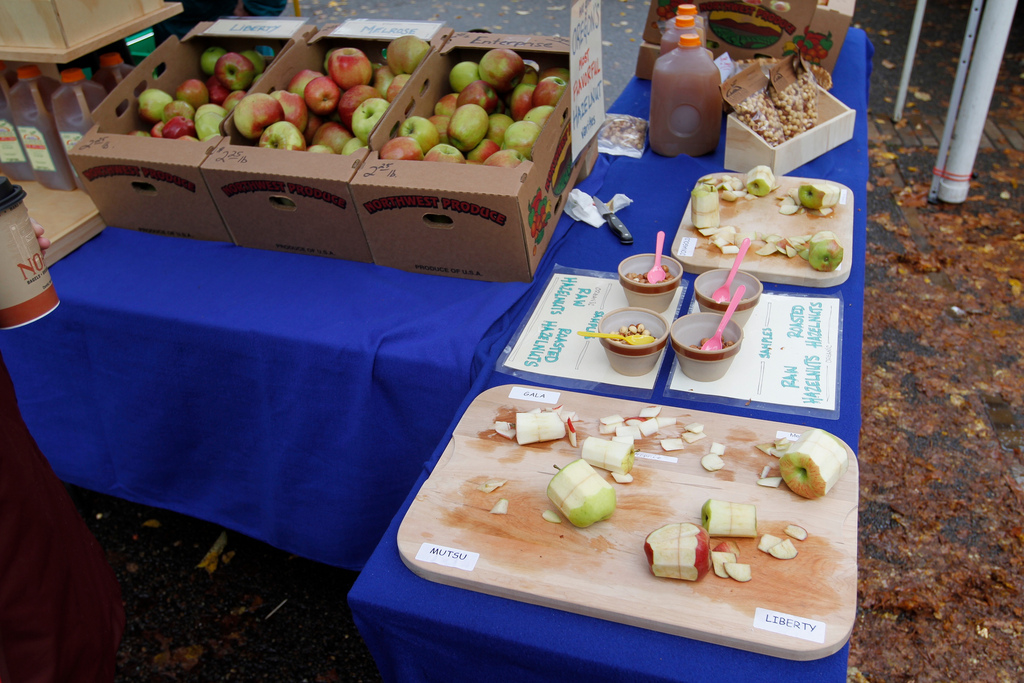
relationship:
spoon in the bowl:
[578, 327, 661, 338] [606, 303, 665, 381]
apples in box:
[149, 6, 566, 292] [80, 1, 636, 323]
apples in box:
[87, 17, 602, 223] [80, 1, 636, 323]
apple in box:
[361, 96, 424, 148] [246, 0, 398, 292]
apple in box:
[400, 96, 444, 159] [363, 16, 632, 306]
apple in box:
[123, 77, 199, 149] [52, 0, 275, 245]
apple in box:
[205, 17, 264, 102] [52, 32, 294, 251]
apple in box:
[356, 118, 436, 185] [333, 6, 623, 326]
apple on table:
[542, 427, 648, 583] [328, 343, 912, 668]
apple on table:
[603, 520, 744, 627] [264, 368, 943, 662]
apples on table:
[518, 375, 773, 464] [302, 276, 996, 668]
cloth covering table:
[35, 187, 554, 572] [22, 25, 904, 602]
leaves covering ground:
[834, 45, 1020, 661] [868, 47, 1011, 672]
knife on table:
[589, 192, 636, 245] [7, 3, 928, 639]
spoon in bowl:
[683, 241, 815, 350] [704, 241, 789, 300]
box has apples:
[335, 29, 658, 304] [287, 3, 638, 299]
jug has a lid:
[655, 21, 733, 177] [652, 10, 711, 62]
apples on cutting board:
[666, 140, 934, 277] [646, 137, 878, 298]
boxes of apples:
[65, 14, 651, 308] [86, 23, 622, 307]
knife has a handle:
[589, 192, 636, 245] [596, 189, 646, 256]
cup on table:
[0, 170, 154, 365] [82, 0, 945, 664]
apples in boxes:
[97, 33, 564, 176] [60, 13, 590, 303]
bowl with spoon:
[667, 310, 745, 393] [696, 282, 755, 365]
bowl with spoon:
[594, 305, 670, 379] [551, 307, 666, 357]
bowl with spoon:
[683, 256, 766, 328] [704, 227, 774, 316]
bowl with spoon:
[611, 249, 687, 320] [626, 214, 689, 301]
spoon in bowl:
[576, 329, 659, 346] [583, 297, 674, 371]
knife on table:
[585, 193, 646, 260] [341, 11, 877, 679]